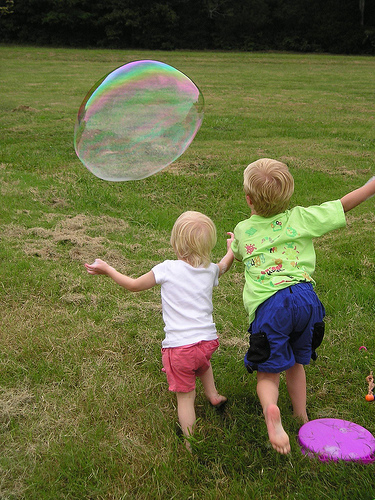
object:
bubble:
[73, 58, 207, 183]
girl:
[83, 207, 234, 456]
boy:
[231, 157, 374, 456]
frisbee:
[298, 417, 375, 462]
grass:
[0, 47, 374, 500]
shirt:
[151, 258, 219, 351]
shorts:
[159, 341, 219, 395]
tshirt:
[231, 198, 347, 329]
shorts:
[243, 280, 326, 377]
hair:
[170, 211, 218, 270]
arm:
[213, 247, 235, 278]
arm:
[107, 262, 164, 293]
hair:
[242, 157, 295, 218]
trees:
[351, 1, 375, 60]